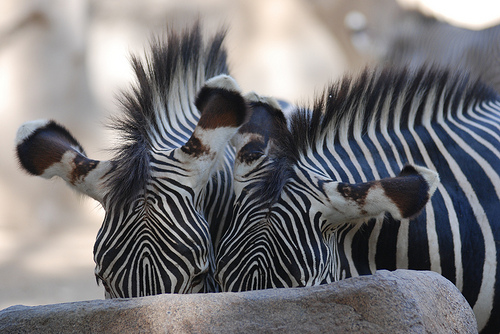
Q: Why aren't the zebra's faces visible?
A: Because they are hidden by the rock.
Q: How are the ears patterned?
A: With black and white stripes.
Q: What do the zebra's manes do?
A: Stick up all bristly.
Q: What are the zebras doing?
A: Eating food out of the stone bowl.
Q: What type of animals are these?
A: Zebras.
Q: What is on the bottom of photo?
A: A stone in front of zebra.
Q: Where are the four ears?
A: On two heads.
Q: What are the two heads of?
A: Zebra.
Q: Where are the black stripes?
A: On head.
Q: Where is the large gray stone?
A: In front of zebras.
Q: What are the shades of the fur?
A: Black and white.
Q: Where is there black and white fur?
A: On zebras.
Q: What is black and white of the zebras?
A: Fur.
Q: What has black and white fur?
A: The zebras.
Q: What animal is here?
A: Zebras.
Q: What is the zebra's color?
A: White and black.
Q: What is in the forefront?
A: A rock.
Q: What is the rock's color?
A: Gray.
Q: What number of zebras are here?
A: 2.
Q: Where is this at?
A: Out in open space.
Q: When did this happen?
A: During the day time.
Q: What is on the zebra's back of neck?
A: Mane.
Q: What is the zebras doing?
A: Grazing.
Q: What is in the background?
A: Blurry background.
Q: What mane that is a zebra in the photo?
A: Black and white zebar.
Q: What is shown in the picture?
A: Two Zebras.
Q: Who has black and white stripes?
A: Two Zebras.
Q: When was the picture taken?
A: In the daytime.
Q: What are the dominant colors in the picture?
A: Black and white.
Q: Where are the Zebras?
A: In front of a trough.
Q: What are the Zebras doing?
A: Standing beside each other.